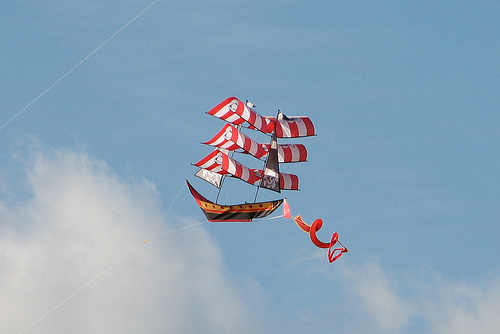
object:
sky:
[2, 1, 500, 334]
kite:
[187, 96, 351, 264]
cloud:
[0, 159, 232, 332]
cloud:
[351, 271, 498, 334]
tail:
[282, 200, 348, 263]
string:
[15, 185, 200, 333]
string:
[2, 2, 156, 132]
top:
[204, 97, 319, 138]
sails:
[195, 96, 315, 194]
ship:
[185, 180, 285, 222]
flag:
[262, 126, 281, 194]